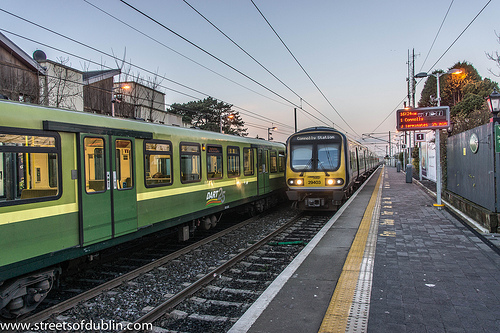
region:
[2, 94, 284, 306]
green passenger train with a yellow stripe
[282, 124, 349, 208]
front of yellow train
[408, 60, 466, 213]
tall outdoor street light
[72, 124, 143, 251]
doors to enter and exit train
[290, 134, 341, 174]
front windshield of train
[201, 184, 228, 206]
name of train company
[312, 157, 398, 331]
yellow stripe on sidewalk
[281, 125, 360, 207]
a yellow train engine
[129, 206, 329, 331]
a set of train tracks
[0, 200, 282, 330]
a set of train tracks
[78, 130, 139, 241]
a green set of train doors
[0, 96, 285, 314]
a green train passenger car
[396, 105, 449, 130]
an electronic sign board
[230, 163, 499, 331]
a passenger train boarding platform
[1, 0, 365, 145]
overhead power lines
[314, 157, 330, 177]
a train windshield wiper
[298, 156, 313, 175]
a train windshield wiper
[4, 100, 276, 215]
The green train to the left.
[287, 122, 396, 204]
The yellow train to the right.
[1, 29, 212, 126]
The houses behind the green train.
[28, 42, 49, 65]
The satelite dish above the second house.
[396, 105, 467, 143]
The lighted sign next to the yellow train.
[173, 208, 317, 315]
The train tracks in front the yellow train.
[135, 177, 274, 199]
The yellow line on the green train.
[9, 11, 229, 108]
The power lines above the trains.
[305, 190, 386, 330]
The yellow line on the train platform.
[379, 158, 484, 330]
The brick train platform displayed.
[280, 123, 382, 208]
a long train on a track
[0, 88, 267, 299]
a green train with a yellow stripe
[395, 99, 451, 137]
a digital sign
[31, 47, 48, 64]
a satellite dish on a roof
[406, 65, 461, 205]
two security lights on a post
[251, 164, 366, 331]
a white line painted on the edge of a plateform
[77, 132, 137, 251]
sliding doors on a train car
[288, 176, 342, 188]
head lights on a train car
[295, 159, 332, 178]
windshield wipers on a train car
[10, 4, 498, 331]
a scene outside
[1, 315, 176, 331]
a watermark on corner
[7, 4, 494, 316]
a scene during the day time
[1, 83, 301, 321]
a green train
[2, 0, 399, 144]
some black power lines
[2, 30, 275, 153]
a group of buildings in the background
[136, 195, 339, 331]
some brown tracks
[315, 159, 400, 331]
a yellow line on the ground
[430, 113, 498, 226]
a gray fence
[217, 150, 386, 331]
a white curb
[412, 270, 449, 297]
small white spots on the sidewalk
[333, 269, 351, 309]
yellow paint on the sidewalk